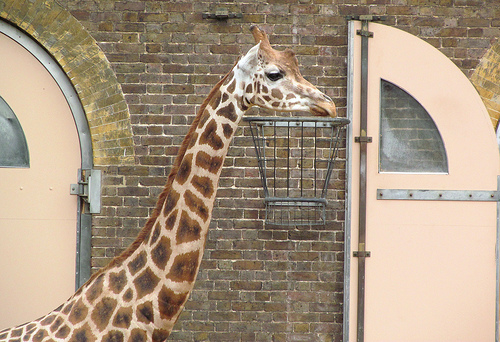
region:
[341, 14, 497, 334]
large light pink door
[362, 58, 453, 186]
window on pink door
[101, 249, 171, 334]
spots on the giraffe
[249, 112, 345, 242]
metal basket on the brick wall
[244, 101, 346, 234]
metal basket is next to the giraffe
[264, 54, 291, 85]
giraffe's dark eyes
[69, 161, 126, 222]
metal door latch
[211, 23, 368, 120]
giraffe's head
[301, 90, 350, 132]
giraffe's mouth is closed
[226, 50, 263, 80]
white section of the giraffe's head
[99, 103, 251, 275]
Giraffe's long neck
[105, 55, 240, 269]
Giraffe's short brown mane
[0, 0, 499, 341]
Brick wall behind the giraffe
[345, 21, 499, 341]
Unused door leaning against the brick wall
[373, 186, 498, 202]
Horizontal metal strip on the unused door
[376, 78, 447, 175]
Glass window in the unused door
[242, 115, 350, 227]
Metal basket on the brick wall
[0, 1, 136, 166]
Arched brick over the door on the left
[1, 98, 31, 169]
Glass window in the door on the left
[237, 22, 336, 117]
Giraffe's entire head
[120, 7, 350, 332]
building is made of brick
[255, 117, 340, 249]
the rack is black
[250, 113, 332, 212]
the rack is metal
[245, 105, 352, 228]
the rack is on building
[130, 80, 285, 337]
the giraffe is spotted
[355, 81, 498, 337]
the doors are peach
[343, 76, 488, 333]
the door is on the buiding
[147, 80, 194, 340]
giraffe in front of building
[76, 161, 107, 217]
the hinges are silver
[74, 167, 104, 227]
hinges on the door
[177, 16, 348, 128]
Face of a giraffe.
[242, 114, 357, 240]
Silver basket on the wall.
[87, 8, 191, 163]
Brick wall of a building.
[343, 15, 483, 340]
Door of a building.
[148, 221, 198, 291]
Brown spots on a giraffe.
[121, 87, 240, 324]
Long neck of a giraffe.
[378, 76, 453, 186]
Window on a door.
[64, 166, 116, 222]
Hinges of a door.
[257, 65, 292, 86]
Right eye of a giraffe.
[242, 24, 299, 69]
Ears and horns of a giraffe.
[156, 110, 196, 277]
the giraffe has a long neck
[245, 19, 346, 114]
the zebra has a small head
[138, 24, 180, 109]
this is a wall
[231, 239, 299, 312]
the wall is made with bricks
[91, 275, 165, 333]
the zebra has different color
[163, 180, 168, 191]
this is the fur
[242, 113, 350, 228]
this is a basket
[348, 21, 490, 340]
this is a gate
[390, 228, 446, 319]
the gate is cream in color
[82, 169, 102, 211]
this is a shutter